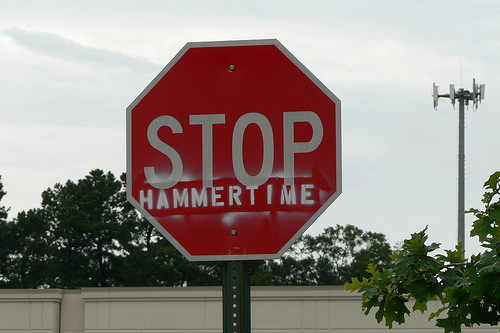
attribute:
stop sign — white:
[127, 37, 340, 266]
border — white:
[182, 38, 276, 47]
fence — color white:
[0, 287, 222, 330]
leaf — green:
[348, 273, 368, 293]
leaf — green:
[412, 296, 431, 311]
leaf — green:
[445, 243, 468, 268]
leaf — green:
[424, 305, 447, 320]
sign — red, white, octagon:
[124, 37, 344, 267]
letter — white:
[184, 182, 211, 211]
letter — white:
[226, 182, 248, 208]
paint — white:
[134, 181, 320, 216]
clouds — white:
[1, 6, 499, 222]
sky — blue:
[0, 3, 494, 273]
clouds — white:
[0, 0, 494, 261]